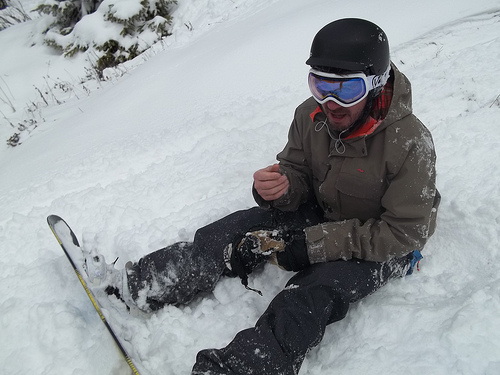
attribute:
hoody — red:
[345, 69, 427, 135]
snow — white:
[2, 5, 493, 374]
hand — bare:
[245, 160, 305, 208]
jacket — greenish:
[235, 89, 476, 239]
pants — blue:
[176, 200, 433, 367]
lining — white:
[302, 65, 369, 83]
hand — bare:
[244, 160, 293, 207]